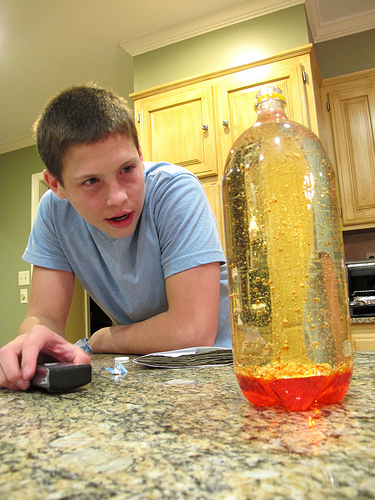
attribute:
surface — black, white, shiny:
[2, 354, 373, 499]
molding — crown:
[116, 1, 374, 57]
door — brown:
[129, 78, 224, 179]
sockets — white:
[15, 271, 30, 303]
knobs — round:
[200, 122, 207, 130]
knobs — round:
[219, 118, 230, 129]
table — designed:
[1, 347, 373, 497]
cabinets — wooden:
[173, 77, 255, 115]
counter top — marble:
[111, 410, 248, 472]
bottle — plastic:
[193, 66, 374, 442]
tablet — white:
[109, 345, 141, 368]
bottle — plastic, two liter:
[221, 83, 355, 411]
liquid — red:
[236, 362, 351, 408]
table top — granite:
[8, 317, 361, 497]